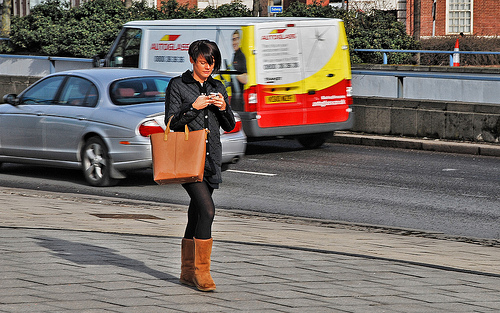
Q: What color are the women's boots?
A: Brown.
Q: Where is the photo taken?
A: On a city street.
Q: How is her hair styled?
A: Short.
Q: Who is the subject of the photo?
A: A Woman.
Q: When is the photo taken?
A: Daytime.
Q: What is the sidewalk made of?
A: Cobblestone.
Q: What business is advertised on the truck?
A: Autoglass.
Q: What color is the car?
A: Silver.